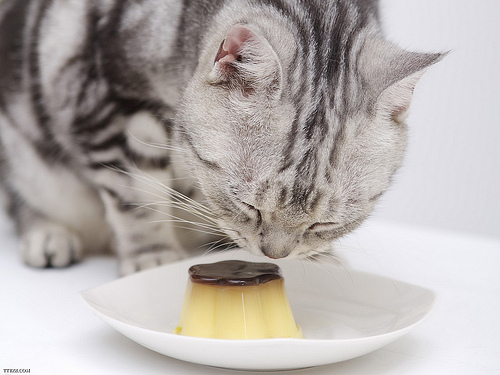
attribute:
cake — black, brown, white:
[189, 259, 292, 336]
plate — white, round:
[112, 242, 414, 359]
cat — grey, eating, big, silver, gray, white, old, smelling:
[4, 2, 430, 265]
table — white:
[4, 208, 478, 374]